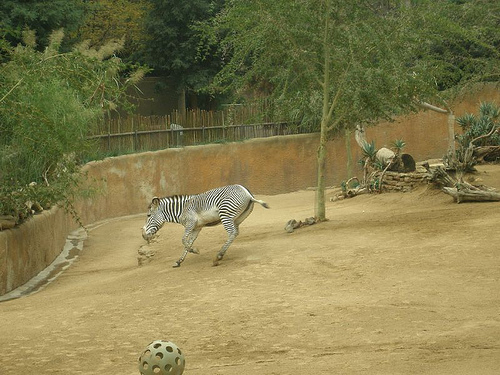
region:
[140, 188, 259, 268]
a running zebra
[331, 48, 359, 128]
branches of a tree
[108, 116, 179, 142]
a fence of sticks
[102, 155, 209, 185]
a wall of stone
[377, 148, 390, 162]
a log of wood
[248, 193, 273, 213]
the tail of a zebra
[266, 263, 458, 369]
a smooth ground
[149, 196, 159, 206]
the ear of a zebra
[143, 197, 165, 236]
the head of a zebra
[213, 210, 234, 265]
the leg of a zebra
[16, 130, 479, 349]
an enclosure for animals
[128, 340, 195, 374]
ball on the ground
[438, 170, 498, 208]
log on the ground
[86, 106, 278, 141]
fence behind the wall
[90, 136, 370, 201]
clay wall enclosing area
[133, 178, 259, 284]
zebra bending over towards ground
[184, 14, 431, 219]
tree in the enclosure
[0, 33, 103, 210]
tree outside the wall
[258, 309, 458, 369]
dirt on the ground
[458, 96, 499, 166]
downed tree in enclosure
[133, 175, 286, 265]
this is a zebra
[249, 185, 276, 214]
this is a tail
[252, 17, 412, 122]
this is a tree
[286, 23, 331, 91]
the leaves are greenin color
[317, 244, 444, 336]
this is the ground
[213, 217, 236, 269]
this is the leg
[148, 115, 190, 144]
this is a fence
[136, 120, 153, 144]
this is a wood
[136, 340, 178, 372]
this is a helmet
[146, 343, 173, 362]
the helmet is white in color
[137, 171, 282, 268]
A black and white zebra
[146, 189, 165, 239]
A black and white zebra's head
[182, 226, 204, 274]
A black and white zebra's feet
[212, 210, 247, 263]
A black and white zebra's feet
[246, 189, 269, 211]
A black and white zebra's tail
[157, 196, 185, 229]
A black and white zebra's neck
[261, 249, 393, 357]
A brown sand ground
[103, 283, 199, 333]
A brown sand ground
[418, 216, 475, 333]
A brown sand ground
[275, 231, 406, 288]
A brown sand ground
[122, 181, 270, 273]
the zebra is running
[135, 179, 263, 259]
zebra has white stripes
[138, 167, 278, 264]
zebra has black stripes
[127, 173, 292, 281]
zebra has a short tail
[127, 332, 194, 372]
ball in pen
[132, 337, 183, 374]
ball has holes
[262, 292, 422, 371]
floor is brown dirt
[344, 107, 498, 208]
logs in the pen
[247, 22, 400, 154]
sparse leaves on the tree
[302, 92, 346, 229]
tree has thin trunk